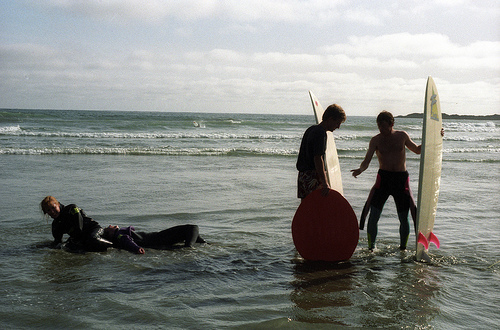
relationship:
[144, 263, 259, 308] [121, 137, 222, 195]
ripples in water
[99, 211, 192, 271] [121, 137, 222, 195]
woman in water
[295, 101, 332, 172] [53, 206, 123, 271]
man in wetsuit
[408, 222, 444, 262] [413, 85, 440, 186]
fins on surfboard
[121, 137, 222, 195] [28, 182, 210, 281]
water with people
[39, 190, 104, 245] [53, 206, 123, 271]
lady in wetsuit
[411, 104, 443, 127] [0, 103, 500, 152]
mountain by ocean